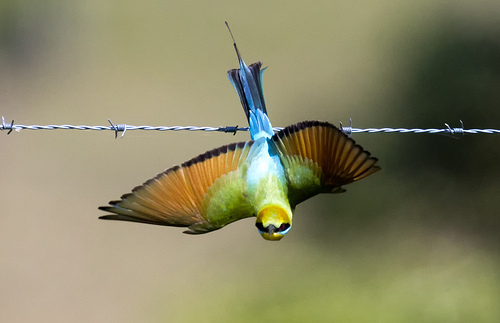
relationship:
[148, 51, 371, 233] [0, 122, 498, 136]
bird on top of barbed wire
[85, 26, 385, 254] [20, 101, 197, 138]
bird on top of fence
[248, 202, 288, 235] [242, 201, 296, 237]
semi-circle around head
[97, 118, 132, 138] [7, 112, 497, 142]
barbs on wire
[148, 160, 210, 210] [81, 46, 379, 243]
feathers on bird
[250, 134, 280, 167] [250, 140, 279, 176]
feathers on bird breast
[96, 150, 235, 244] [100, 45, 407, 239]
wing on bird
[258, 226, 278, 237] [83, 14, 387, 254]
beak on bird